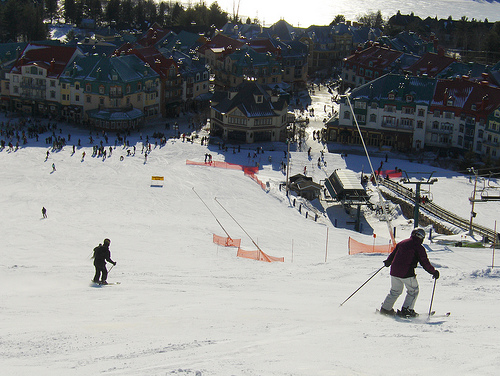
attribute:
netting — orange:
[210, 233, 242, 247]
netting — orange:
[235, 246, 286, 261]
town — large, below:
[0, 10, 499, 170]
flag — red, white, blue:
[150, 175, 163, 188]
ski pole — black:
[338, 263, 387, 308]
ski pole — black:
[426, 277, 437, 319]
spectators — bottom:
[4, 121, 167, 161]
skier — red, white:
[379, 220, 441, 320]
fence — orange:
[206, 227, 289, 267]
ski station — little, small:
[286, 161, 387, 235]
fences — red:
[208, 228, 391, 265]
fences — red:
[179, 155, 244, 169]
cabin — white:
[337, 96, 498, 142]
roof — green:
[352, 94, 499, 116]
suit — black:
[87, 244, 112, 278]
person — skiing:
[376, 222, 446, 322]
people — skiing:
[84, 218, 444, 322]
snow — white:
[208, 320, 497, 371]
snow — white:
[149, 275, 272, 364]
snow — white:
[1, 117, 499, 374]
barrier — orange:
[213, 233, 284, 263]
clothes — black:
[94, 243, 112, 279]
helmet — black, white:
[409, 228, 427, 241]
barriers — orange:
[210, 230, 286, 262]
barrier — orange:
[187, 158, 264, 173]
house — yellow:
[60, 51, 162, 116]